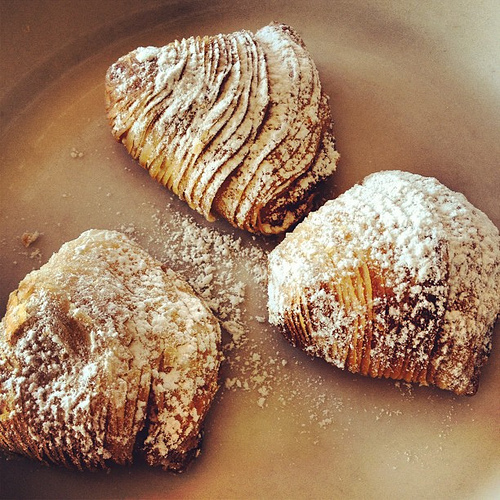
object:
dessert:
[104, 20, 341, 235]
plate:
[0, 0, 500, 499]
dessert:
[266, 168, 499, 396]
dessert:
[0, 228, 225, 476]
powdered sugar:
[143, 200, 330, 427]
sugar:
[144, 27, 302, 209]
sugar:
[295, 174, 448, 354]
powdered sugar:
[23, 264, 186, 433]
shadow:
[0, 0, 202, 129]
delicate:
[0, 18, 499, 473]